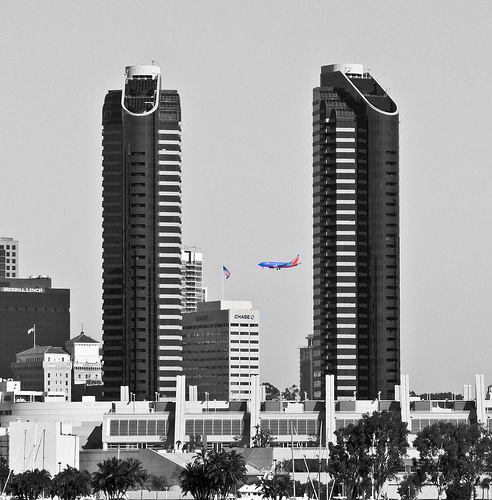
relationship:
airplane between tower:
[258, 255, 300, 272] [102, 65, 185, 401]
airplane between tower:
[258, 255, 300, 272] [314, 63, 401, 399]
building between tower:
[182, 301, 259, 400] [102, 65, 185, 401]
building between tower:
[182, 301, 259, 400] [314, 63, 401, 399]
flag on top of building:
[222, 266, 232, 280] [182, 301, 259, 400]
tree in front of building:
[52, 464, 93, 499] [8, 421, 79, 481]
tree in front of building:
[204, 450, 250, 499] [102, 374, 491, 453]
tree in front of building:
[263, 473, 291, 499] [102, 374, 491, 453]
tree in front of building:
[354, 409, 408, 499] [182, 301, 259, 400]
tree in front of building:
[413, 423, 479, 499] [182, 301, 259, 400]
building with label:
[1, 278, 71, 380] [3, 286, 45, 293]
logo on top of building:
[235, 315, 256, 320] [182, 301, 259, 400]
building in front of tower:
[102, 374, 491, 453] [102, 65, 185, 401]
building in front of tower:
[102, 374, 491, 453] [314, 63, 401, 399]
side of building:
[183, 309, 229, 398] [182, 301, 259, 400]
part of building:
[196, 300, 253, 311] [182, 301, 259, 400]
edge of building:
[229, 308, 260, 401] [182, 301, 259, 400]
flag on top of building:
[26, 326, 34, 335] [10, 346, 72, 402]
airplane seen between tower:
[258, 255, 300, 272] [102, 65, 185, 401]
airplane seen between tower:
[258, 255, 300, 272] [314, 63, 401, 399]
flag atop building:
[222, 266, 232, 280] [182, 301, 259, 400]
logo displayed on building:
[235, 315, 256, 320] [182, 301, 259, 400]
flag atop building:
[26, 326, 34, 335] [10, 346, 72, 402]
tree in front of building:
[354, 409, 408, 499] [102, 374, 491, 453]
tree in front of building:
[413, 423, 479, 499] [102, 374, 491, 453]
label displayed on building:
[3, 286, 45, 293] [1, 278, 71, 380]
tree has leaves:
[204, 450, 250, 499] [205, 449, 247, 491]